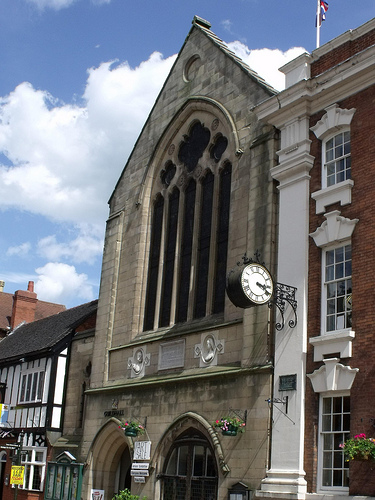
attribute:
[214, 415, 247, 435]
plant — hanging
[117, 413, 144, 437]
plant — hanging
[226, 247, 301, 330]
clock — black, white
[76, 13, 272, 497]
building — large, old, stone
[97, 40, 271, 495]
church — big, brown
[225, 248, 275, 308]
clock — black, white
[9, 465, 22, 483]
signboard — squared, yellow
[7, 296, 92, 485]
house — white, black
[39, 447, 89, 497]
windows — green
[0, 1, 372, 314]
sky — blue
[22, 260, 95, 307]
cloud — white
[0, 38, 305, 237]
cloud — white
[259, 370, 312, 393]
sign — black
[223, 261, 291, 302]
clock — white, black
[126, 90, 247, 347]
window — brown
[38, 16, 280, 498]
building — brown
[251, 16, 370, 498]
building — old